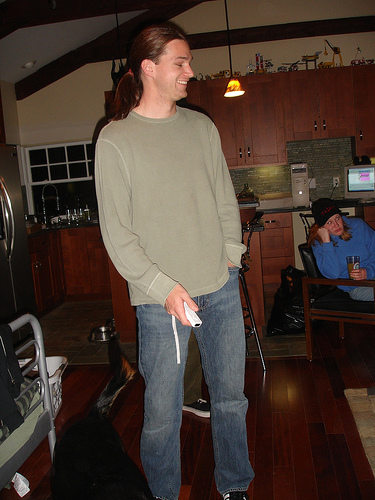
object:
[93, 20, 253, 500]
man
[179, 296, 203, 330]
wii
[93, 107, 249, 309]
shirt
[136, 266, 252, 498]
jeans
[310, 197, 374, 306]
person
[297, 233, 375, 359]
chair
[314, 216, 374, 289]
sweatshirt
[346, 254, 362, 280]
cup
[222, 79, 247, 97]
light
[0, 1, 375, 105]
ceiling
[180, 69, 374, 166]
cabinets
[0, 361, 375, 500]
floor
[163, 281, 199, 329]
hand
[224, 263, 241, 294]
pocket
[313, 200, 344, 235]
head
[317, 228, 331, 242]
hand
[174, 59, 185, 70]
eyes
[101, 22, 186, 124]
hair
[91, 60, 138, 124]
ponytail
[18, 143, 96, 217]
window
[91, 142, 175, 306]
long sleeves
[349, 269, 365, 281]
hand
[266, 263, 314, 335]
bag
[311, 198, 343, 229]
hat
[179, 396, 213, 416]
shoe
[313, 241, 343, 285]
sleeve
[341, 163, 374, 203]
monitor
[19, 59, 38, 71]
light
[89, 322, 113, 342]
dish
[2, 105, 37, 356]
refrigerator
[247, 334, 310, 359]
rug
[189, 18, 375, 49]
beam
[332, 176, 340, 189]
outlet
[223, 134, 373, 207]
wall